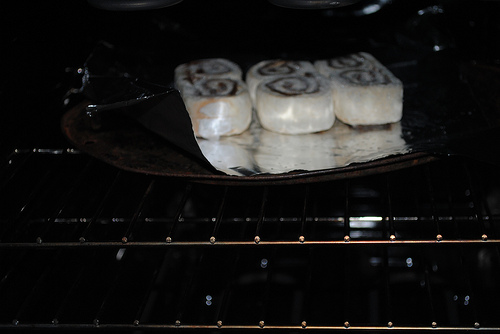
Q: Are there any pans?
A: Yes, there is a pan.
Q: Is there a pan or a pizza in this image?
A: Yes, there is a pan.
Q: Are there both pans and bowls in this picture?
A: No, there is a pan but no bowls.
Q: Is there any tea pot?
A: No, there are no tea pots.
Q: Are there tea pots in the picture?
A: No, there are no tea pots.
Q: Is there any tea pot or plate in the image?
A: No, there are no tea pots or plates.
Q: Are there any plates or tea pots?
A: No, there are no tea pots or plates.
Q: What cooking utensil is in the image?
A: The cooking utensil is a pan.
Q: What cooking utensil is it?
A: The cooking utensil is a pan.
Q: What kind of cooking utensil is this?
A: This is a pan.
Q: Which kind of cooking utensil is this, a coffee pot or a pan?
A: This is a pan.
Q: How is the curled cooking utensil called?
A: The cooking utensil is a pan.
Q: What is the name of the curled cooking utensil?
A: The cooking utensil is a pan.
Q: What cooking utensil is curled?
A: The cooking utensil is a pan.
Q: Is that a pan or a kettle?
A: That is a pan.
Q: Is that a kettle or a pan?
A: That is a pan.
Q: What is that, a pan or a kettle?
A: That is a pan.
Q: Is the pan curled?
A: Yes, the pan is curled.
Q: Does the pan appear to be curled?
A: Yes, the pan is curled.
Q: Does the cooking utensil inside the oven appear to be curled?
A: Yes, the pan is curled.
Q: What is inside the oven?
A: The pan is inside the oven.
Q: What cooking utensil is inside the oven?
A: The cooking utensil is a pan.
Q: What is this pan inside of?
A: The pan is inside the oven.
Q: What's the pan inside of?
A: The pan is inside the oven.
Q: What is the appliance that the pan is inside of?
A: The appliance is an oven.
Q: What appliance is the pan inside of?
A: The pan is inside the oven.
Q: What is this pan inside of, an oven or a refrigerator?
A: The pan is inside an oven.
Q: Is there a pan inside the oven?
A: Yes, there is a pan inside the oven.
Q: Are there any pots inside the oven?
A: No, there is a pan inside the oven.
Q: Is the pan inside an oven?
A: Yes, the pan is inside an oven.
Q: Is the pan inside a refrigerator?
A: No, the pan is inside an oven.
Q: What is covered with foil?
A: The pan is covered with foil.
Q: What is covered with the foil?
A: The pan is covered with foil.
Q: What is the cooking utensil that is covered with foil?
A: The cooking utensil is a pan.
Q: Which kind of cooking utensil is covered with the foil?
A: The cooking utensil is a pan.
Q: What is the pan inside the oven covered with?
A: The pan is covered with foil.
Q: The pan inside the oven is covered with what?
A: The pan is covered with foil.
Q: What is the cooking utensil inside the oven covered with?
A: The pan is covered with foil.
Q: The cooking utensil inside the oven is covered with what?
A: The pan is covered with foil.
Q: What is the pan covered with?
A: The pan is covered with foil.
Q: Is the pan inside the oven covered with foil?
A: Yes, the pan is covered with foil.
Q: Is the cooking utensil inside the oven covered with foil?
A: Yes, the pan is covered with foil.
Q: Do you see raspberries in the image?
A: No, there are no raspberries.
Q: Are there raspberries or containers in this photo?
A: No, there are no raspberries or containers.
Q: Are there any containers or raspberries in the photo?
A: No, there are no raspberries or containers.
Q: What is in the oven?
A: The cinnamon roll is in the oven.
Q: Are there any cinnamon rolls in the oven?
A: Yes, there is a cinnamon roll in the oven.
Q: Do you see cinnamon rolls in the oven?
A: Yes, there is a cinnamon roll in the oven.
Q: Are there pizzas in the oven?
A: No, there is a cinnamon roll in the oven.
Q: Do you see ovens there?
A: Yes, there is an oven.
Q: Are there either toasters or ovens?
A: Yes, there is an oven.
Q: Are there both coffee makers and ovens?
A: No, there is an oven but no coffee makers.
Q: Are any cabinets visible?
A: No, there are no cabinets.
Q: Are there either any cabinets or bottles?
A: No, there are no cabinets or bottles.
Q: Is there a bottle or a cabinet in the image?
A: No, there are no cabinets or bottles.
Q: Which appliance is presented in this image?
A: The appliance is an oven.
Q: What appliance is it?
A: The appliance is an oven.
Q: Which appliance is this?
A: This is an oven.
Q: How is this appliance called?
A: This is an oven.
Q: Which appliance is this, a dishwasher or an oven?
A: This is an oven.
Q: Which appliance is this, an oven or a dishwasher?
A: This is an oven.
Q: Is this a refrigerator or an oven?
A: This is an oven.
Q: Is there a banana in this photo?
A: No, there are no bananas.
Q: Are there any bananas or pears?
A: No, there are no bananas or pears.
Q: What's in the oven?
A: The cinnamon roll is in the oven.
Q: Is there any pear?
A: No, there are no pears.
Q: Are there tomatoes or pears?
A: No, there are no pears or tomatoes.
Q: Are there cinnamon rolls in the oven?
A: Yes, there is a cinnamon roll in the oven.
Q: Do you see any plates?
A: No, there are no plates.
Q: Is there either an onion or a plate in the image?
A: No, there are no plates or onions.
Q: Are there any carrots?
A: No, there are no carrots.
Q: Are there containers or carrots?
A: No, there are no carrots or containers.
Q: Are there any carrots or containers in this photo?
A: No, there are no carrots or containers.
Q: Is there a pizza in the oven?
A: No, there is a cinnamon roll in the oven.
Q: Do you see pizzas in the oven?
A: No, there is a cinnamon roll in the oven.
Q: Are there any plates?
A: No, there are no plates.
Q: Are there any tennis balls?
A: No, there are no tennis balls.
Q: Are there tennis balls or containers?
A: No, there are no tennis balls or containers.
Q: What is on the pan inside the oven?
A: The foil is on the pan.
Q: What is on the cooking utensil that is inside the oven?
A: The foil is on the pan.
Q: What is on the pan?
A: The foil is on the pan.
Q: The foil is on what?
A: The foil is on the pan.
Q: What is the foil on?
A: The foil is on the pan.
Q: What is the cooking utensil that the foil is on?
A: The cooking utensil is a pan.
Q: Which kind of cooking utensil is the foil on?
A: The foil is on the pan.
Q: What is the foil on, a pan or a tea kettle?
A: The foil is on a pan.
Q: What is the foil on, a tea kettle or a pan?
A: The foil is on a pan.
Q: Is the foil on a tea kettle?
A: No, the foil is on a pan.